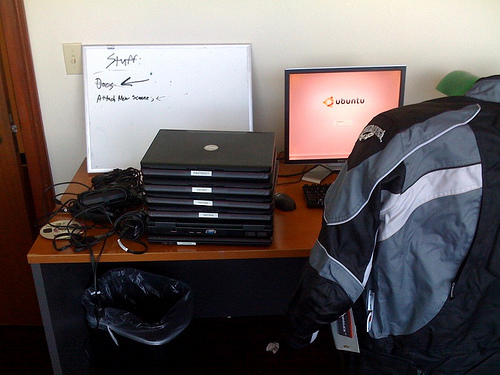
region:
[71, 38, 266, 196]
A white board.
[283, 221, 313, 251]
The table is brown.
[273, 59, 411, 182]
A computer monitor.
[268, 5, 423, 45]
The wall is white.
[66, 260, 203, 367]
A trash can.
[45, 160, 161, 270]
A lot of wires.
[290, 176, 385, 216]
A keyboard is on the desk.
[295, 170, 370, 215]
The keyboard is black.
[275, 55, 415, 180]
The computer monitor is on.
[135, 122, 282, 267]
A stack of black laptops.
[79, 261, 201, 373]
THE TRASH CAN IS BLACK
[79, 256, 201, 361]
THE TRASH CAN HAS A CLEAR PLASTIC LINER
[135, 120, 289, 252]
THE LAPTOPS ARE STACKED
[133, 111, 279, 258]
THE LAPTOPS ARE BLACK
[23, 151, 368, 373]
THE DESK HAS A BROWN TOP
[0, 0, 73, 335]
THE DOOR IS BROWN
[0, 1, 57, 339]
THE DOOR IS WOOD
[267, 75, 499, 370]
THE JACKET IS GREY AND BLACK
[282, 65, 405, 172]
THE MONITOR IS PINK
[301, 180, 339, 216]
THE KEYBOARD IS BLACK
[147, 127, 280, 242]
A stack of laptops.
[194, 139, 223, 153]
Decal on the laptop.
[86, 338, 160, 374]
The trashcan is black.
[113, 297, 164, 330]
The trash bag is clear.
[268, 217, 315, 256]
The desk is brown.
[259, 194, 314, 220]
The mouse is black.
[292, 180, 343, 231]
The keyboard is black.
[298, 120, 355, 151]
The monitor is on.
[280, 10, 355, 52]
The wall is white.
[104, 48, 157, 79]
"Stuff" written on the dry erase board.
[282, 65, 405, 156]
a black monitor on a desk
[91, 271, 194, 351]
a black wastebasket with a plastic bag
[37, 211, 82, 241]
a CD on a desk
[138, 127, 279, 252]
a stack of closed laptops on a desk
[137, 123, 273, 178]
a black laptop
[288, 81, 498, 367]
a ski coat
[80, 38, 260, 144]
a white board propped on the wall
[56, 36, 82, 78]
a beige light switch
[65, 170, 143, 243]
a bunch of wires on the desk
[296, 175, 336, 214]
edge of a black keyboard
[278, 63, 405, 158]
a partly blocked computer moniter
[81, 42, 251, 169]
a white dry erase board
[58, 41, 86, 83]
an electrical switch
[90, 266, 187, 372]
an empty trash can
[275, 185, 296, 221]
a computer mouse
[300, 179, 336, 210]
part of a computer keyboard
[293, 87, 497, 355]
a blue and white jacket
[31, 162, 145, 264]
a jumble of cords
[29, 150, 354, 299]
part of the top of a desk